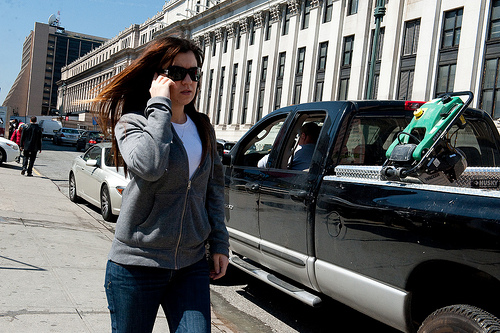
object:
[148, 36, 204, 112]
head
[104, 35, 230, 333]
woman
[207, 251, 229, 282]
hand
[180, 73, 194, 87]
nose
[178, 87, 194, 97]
mouth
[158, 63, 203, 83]
sunglasses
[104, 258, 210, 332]
jeans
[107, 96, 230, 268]
hoody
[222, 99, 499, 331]
truck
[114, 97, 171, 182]
arm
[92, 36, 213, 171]
hair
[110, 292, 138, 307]
part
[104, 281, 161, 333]
thigh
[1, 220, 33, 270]
part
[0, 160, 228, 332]
floor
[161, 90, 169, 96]
part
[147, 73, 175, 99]
hand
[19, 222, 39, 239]
part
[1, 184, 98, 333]
line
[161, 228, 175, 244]
part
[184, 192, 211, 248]
pocket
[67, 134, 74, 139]
part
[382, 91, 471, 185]
equipment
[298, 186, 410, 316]
door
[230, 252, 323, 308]
step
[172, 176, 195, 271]
zipper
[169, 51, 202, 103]
face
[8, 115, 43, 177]
people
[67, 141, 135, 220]
car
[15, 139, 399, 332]
road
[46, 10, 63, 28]
dish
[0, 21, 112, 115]
building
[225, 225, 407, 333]
trim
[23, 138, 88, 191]
asphalt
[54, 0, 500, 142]
building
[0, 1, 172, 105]
skies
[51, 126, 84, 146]
car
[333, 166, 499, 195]
box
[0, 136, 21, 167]
car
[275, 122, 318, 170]
person